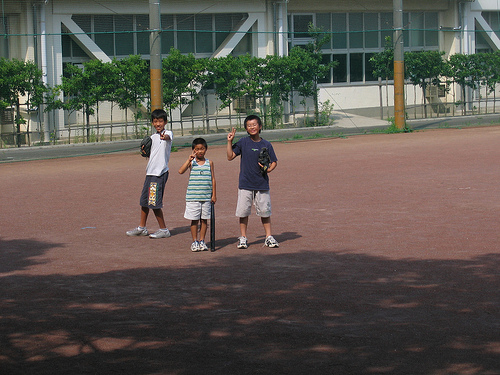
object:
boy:
[225, 114, 281, 251]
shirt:
[228, 134, 279, 192]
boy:
[123, 107, 175, 240]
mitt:
[139, 134, 154, 162]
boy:
[175, 137, 220, 253]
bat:
[208, 198, 216, 255]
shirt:
[183, 157, 217, 204]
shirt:
[140, 129, 174, 179]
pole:
[147, 1, 164, 142]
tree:
[0, 55, 48, 149]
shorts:
[136, 170, 170, 212]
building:
[0, 1, 500, 153]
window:
[70, 14, 95, 60]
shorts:
[183, 198, 215, 221]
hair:
[243, 114, 263, 137]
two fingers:
[231, 127, 236, 134]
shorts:
[234, 188, 271, 221]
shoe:
[265, 234, 280, 247]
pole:
[388, 0, 406, 134]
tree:
[371, 38, 451, 114]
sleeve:
[266, 140, 278, 165]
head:
[149, 107, 166, 133]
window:
[91, 10, 115, 61]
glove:
[256, 142, 273, 178]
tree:
[40, 59, 132, 146]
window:
[112, 10, 137, 57]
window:
[133, 12, 156, 57]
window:
[157, 10, 175, 59]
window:
[173, 12, 196, 56]